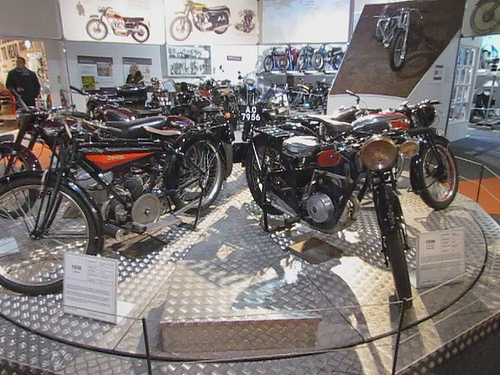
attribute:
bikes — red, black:
[52, 34, 439, 271]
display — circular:
[0, 108, 497, 365]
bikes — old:
[10, 78, 466, 277]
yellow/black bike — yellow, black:
[153, 0, 233, 41]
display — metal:
[0, 71, 498, 372]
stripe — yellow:
[458, 155, 494, 187]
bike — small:
[259, 44, 294, 72]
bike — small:
[287, 37, 326, 72]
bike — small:
[313, 43, 340, 74]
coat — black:
[8, 72, 40, 99]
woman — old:
[116, 58, 150, 105]